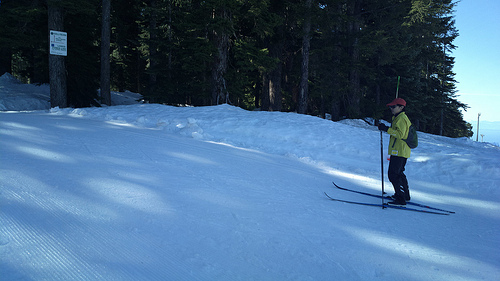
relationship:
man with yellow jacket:
[378, 98, 418, 207] [391, 118, 411, 139]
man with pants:
[378, 98, 418, 207] [379, 152, 409, 204]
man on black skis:
[378, 97, 418, 207] [323, 181, 455, 214]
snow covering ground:
[0, 73, 498, 278] [2, 73, 499, 277]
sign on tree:
[48, 29, 67, 56] [47, 4, 71, 105]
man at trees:
[378, 98, 418, 207] [7, 5, 474, 135]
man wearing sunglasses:
[378, 98, 418, 207] [384, 104, 404, 115]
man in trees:
[378, 98, 418, 207] [7, 5, 474, 135]